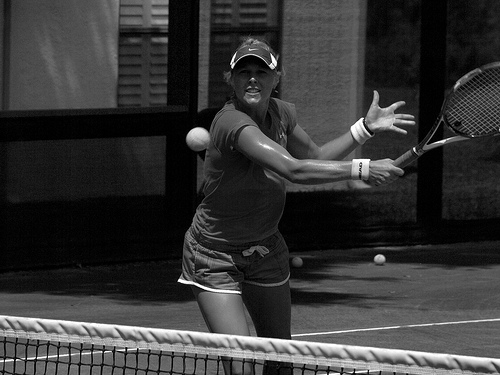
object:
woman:
[175, 36, 416, 369]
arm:
[223, 111, 370, 185]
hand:
[364, 89, 416, 139]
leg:
[188, 285, 254, 375]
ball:
[187, 126, 211, 152]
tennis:
[8, 9, 493, 369]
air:
[11, 12, 485, 360]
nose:
[245, 75, 259, 86]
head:
[222, 34, 285, 108]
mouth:
[240, 84, 263, 97]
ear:
[272, 68, 282, 93]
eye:
[237, 65, 250, 78]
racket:
[392, 56, 495, 170]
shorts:
[177, 222, 292, 296]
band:
[350, 156, 371, 182]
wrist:
[350, 158, 371, 182]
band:
[350, 115, 376, 147]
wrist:
[349, 117, 372, 149]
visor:
[228, 40, 280, 75]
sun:
[11, 0, 494, 365]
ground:
[0, 243, 500, 375]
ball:
[372, 252, 387, 265]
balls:
[292, 256, 304, 268]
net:
[0, 314, 493, 375]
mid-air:
[11, 11, 496, 310]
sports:
[0, 12, 500, 352]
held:
[361, 154, 408, 187]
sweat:
[240, 125, 350, 185]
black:
[0, 0, 500, 365]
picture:
[0, 0, 500, 375]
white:
[8, 10, 493, 367]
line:
[0, 311, 500, 367]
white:
[5, 312, 494, 366]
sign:
[245, 46, 262, 52]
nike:
[247, 45, 260, 50]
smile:
[244, 87, 262, 97]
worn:
[225, 37, 281, 108]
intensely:
[200, 37, 416, 195]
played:
[167, 23, 496, 375]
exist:
[385, 54, 500, 183]